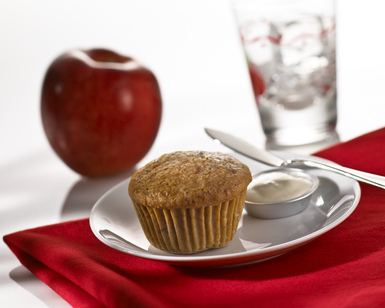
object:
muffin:
[127, 152, 253, 254]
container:
[243, 165, 321, 219]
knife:
[204, 126, 385, 190]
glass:
[234, 1, 340, 149]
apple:
[41, 48, 162, 179]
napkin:
[2, 127, 384, 308]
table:
[1, 54, 384, 305]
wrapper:
[129, 188, 249, 253]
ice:
[243, 19, 281, 68]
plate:
[89, 149, 361, 268]